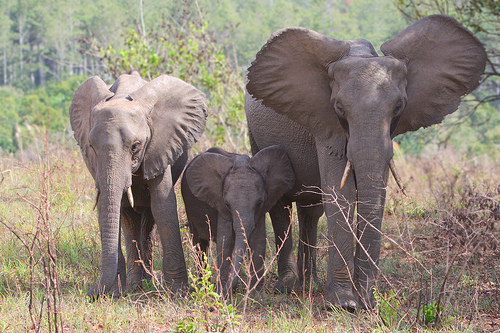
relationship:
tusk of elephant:
[387, 153, 418, 203] [241, 42, 425, 309]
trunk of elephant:
[95, 177, 126, 306] [241, 42, 425, 309]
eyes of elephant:
[320, 89, 422, 127] [241, 42, 425, 309]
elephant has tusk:
[241, 42, 425, 309] [387, 153, 418, 203]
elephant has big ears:
[241, 42, 425, 309] [391, 39, 488, 142]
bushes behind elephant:
[164, 26, 250, 95] [241, 42, 425, 309]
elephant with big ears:
[241, 42, 425, 309] [391, 39, 488, 142]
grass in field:
[60, 228, 88, 246] [407, 218, 499, 316]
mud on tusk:
[390, 168, 417, 192] [387, 153, 418, 203]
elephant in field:
[241, 42, 425, 309] [407, 218, 499, 316]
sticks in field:
[16, 190, 67, 323] [407, 218, 499, 316]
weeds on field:
[467, 203, 480, 244] [407, 218, 499, 316]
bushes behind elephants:
[164, 26, 250, 95] [62, 17, 486, 309]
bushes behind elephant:
[94, 20, 250, 149] [241, 42, 425, 309]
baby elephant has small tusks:
[177, 138, 305, 305] [221, 229, 272, 231]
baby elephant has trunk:
[177, 138, 305, 305] [95, 177, 126, 306]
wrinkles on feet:
[330, 265, 359, 287] [311, 250, 400, 325]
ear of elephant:
[254, 152, 298, 220] [241, 42, 425, 309]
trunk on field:
[95, 177, 126, 306] [407, 218, 499, 316]